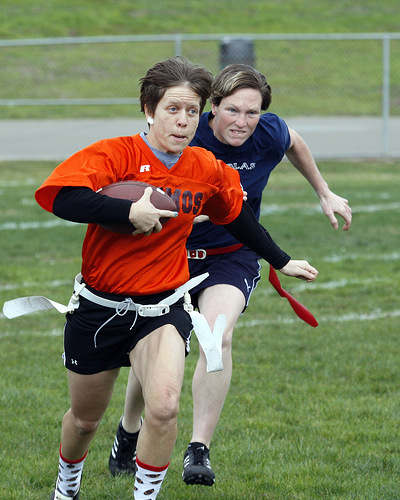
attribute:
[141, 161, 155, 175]
letter — white, r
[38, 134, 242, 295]
shirt — orange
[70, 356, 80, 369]
emblem — white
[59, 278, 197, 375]
shorts — black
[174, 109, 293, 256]
shirt — blue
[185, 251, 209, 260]
belt fastener — white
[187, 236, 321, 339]
belt — red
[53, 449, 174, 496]
socks — white, red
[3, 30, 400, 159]
fence — chain linked, gray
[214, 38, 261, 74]
garbage can — black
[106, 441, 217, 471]
stripes — white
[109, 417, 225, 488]
cleats — player's, white, black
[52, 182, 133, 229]
sleeve — black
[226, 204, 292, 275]
sleeve — black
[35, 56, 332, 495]
person — wearing, running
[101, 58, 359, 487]
person — running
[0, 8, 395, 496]
grass — green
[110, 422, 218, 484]
shoes — black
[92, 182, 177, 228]
ball — brown, carried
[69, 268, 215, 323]
belt — white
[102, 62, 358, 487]
player — pursuing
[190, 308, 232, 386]
flag — red, white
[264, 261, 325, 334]
flag — red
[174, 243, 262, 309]
shorts — blue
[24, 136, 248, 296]
jersey — orange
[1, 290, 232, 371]
flags — white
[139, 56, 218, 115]
hair — brown